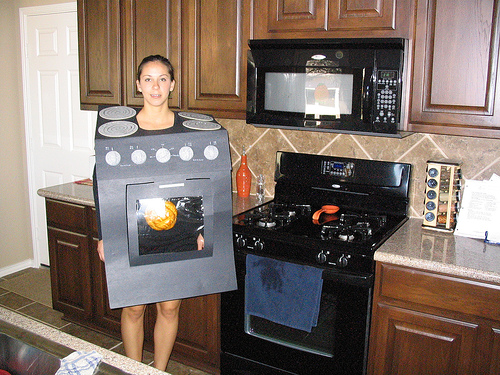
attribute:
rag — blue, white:
[56, 355, 113, 374]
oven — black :
[217, 148, 410, 373]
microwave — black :
[240, 34, 411, 132]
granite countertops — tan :
[374, 215, 498, 282]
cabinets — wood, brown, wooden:
[74, 0, 255, 122]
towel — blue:
[243, 252, 324, 333]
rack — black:
[236, 250, 373, 288]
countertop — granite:
[383, 222, 498, 277]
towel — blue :
[240, 250, 332, 340]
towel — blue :
[240, 249, 327, 335]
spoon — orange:
[310, 201, 340, 224]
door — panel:
[117, 166, 239, 287]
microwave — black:
[236, 17, 413, 147]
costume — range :
[88, 100, 264, 291]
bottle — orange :
[235, 152, 251, 197]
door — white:
[19, 5, 79, 267]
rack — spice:
[401, 157, 482, 234]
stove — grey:
[94, 101, 239, 308]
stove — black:
[220, 147, 412, 373]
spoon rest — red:
[312, 205, 338, 222]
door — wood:
[8, 3, 105, 292]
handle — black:
[314, 250, 353, 273]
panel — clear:
[127, 186, 213, 249]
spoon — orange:
[312, 199, 340, 229]